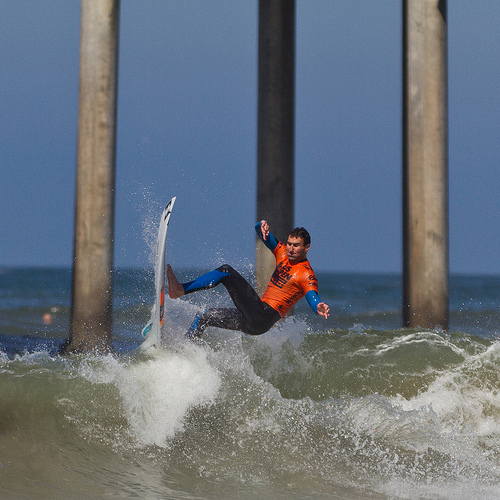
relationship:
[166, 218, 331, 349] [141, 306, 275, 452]
man on boar surf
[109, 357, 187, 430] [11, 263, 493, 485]
foam of ocean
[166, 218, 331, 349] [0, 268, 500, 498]
man over ocean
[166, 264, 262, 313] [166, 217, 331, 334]
leg of a man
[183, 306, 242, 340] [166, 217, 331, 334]
leg of a man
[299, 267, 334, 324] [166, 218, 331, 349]
arm of man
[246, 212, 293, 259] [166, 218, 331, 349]
arm of man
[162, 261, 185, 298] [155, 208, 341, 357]
foot to man